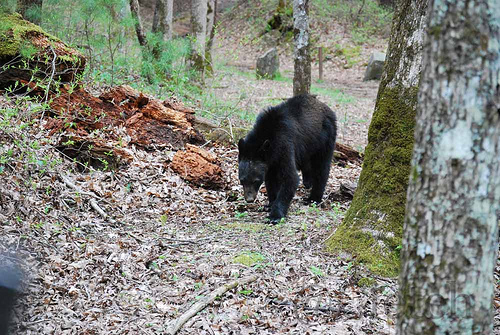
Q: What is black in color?
A: The bear fur.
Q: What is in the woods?
A: An animal.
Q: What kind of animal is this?
A: A bear.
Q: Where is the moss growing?
A: On the tree.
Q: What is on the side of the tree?
A: Moss.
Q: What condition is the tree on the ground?
A: Rotten.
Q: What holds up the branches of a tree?
A: The trunk.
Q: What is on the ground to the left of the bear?
A: A dead tree.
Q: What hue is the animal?
A: Dark.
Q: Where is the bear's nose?
A: By the ground.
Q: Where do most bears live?
A: In the woods.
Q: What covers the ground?
A: Leaves and sticks.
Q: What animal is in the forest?
A: A bear.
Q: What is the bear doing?
A: Foraging.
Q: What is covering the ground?
A: Leaves.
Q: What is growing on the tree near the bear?
A: Moss.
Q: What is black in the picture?
A: A bear.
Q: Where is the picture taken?
A: A forest.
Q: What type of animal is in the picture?
A: A bear.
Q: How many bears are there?
A: One.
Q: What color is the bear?
A: Black.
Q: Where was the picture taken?
A: In a forest.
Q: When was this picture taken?
A: During the day.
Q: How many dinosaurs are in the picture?
A: Zero.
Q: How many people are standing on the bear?
A: Zero.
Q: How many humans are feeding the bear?
A: Zero.